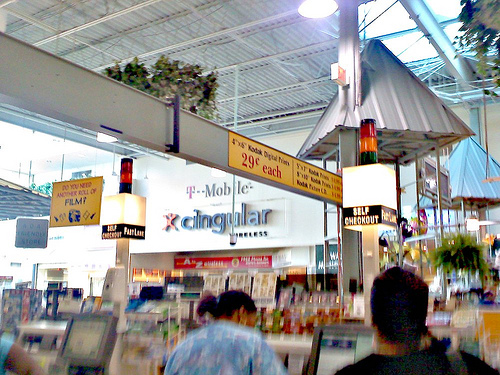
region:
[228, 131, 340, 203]
yellow sign with red numbers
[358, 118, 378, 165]
three color cylinder shaped light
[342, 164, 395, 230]
cube shaped glowing white light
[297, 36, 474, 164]
steep pointed gray roof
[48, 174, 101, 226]
yellow sign with red words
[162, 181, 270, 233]
two stacked company logos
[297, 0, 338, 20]
glowing round white light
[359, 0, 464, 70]
sunlight through roof skylight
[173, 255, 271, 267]
long red rectangle sign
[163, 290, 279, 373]
back of woman with pony tail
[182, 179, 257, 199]
A T-Mobile emblem on the wall.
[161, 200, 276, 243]
A Cingular Wireless emblem on a wall.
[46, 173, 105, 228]
A dark yellow square sign.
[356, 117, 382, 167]
A red, orange, and green light.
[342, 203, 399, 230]
A self checkout sign.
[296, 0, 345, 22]
A light mounted in the ceiling.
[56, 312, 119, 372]
A cash register monitor.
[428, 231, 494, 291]
A plant in a store.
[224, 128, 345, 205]
A sign advertising Kodak prints.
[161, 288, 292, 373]
A woman in a colorful shirt.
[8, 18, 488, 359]
People are in a local mall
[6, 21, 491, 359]
People are doing some shopping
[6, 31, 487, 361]
Consumers are spending their money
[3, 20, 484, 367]
People are shopping in a store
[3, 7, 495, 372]
People are shopping for cell phones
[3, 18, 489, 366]
People are out in the daytime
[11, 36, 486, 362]
People are enjoying their day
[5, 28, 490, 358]
Businesses are open for customers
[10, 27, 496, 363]
Customers are selecting their purchases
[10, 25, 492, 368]
Regular business is taking place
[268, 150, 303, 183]
part of a banner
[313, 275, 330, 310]
part of a bottle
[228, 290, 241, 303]
hair of a lady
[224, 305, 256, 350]
part of a shoilder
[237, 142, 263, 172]
the text saying 29 cents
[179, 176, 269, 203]
a T-Mobile Sign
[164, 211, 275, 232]
a Cingular sign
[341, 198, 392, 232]
self checkout for shopping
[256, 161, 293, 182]
the text saying each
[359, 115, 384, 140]
red light above self checkout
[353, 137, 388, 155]
yellow light above self checkout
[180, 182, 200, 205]
The letter T for T-Mobile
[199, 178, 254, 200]
the word Mobile from T-Mobile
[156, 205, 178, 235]
the logo of cingular